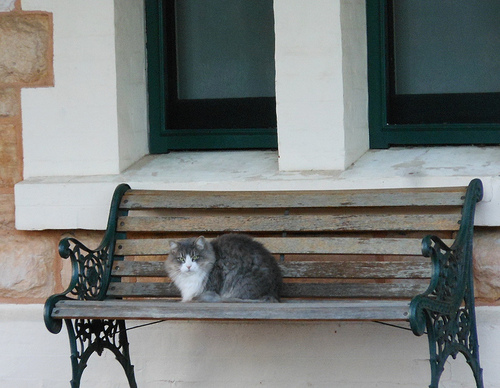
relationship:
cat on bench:
[163, 233, 282, 304] [43, 179, 484, 385]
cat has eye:
[163, 233, 282, 304] [174, 255, 204, 263]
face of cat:
[168, 242, 207, 274] [163, 233, 282, 304]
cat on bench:
[170, 229, 277, 305] [43, 179, 484, 385]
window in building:
[388, 0, 498, 128] [0, 1, 499, 384]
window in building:
[142, 0, 276, 156] [0, 1, 499, 384]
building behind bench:
[0, 1, 499, 384] [43, 179, 484, 385]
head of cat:
[164, 230, 208, 276] [163, 233, 282, 304]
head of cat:
[167, 235, 207, 275] [163, 233, 282, 304]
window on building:
[363, 1, 499, 151] [0, 1, 499, 384]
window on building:
[142, 0, 276, 156] [0, 1, 499, 384]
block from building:
[0, 233, 61, 302] [0, 1, 499, 384]